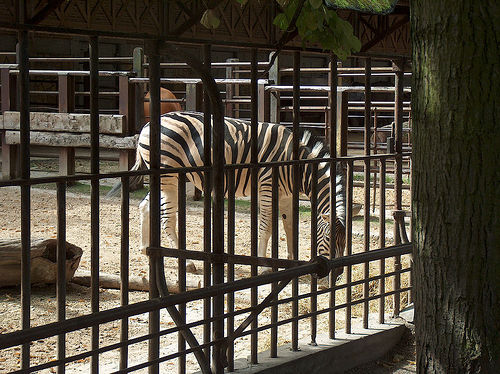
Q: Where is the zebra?
A: In the cage.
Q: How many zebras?
A: 1.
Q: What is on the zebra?
A: Stripes.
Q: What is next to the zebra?
A: Gate.